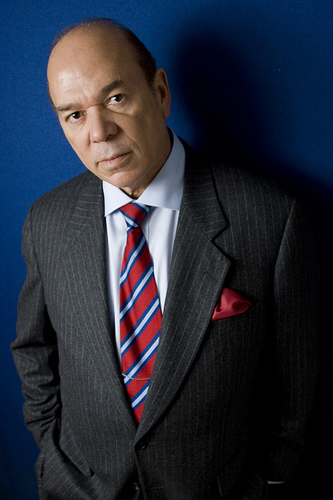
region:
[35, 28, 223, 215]
a man standing inside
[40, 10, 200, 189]
a man with short hair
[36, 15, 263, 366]
a man wearing a shirt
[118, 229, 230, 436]
white blue red tie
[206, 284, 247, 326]
handkerchief in man suit jacket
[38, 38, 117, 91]
man with a bald head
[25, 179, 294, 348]
man wearing a pinstrip jacket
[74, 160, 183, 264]
man wearing a white shirt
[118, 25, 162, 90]
man with black hair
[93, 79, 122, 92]
man with bushy eyebrow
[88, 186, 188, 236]
man wearing a white shirt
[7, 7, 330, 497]
a man looking at the camera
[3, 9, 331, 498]
a person posing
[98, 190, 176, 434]
a red, white, and blue tie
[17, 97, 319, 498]
a black suit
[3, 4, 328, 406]
a blue background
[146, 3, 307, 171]
a shadow in the background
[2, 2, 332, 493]
a single person in image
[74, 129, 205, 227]
a white collar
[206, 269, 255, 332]
a red object in the pocket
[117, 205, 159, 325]
this is a tie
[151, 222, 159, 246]
this is a white shirt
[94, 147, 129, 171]
the mouth if a man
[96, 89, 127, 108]
the eye of the man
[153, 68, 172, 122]
the ear of the man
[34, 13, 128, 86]
man has bald head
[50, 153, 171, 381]
man has white shirt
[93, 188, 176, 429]
red white and blue tie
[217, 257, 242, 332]
man has red kerchief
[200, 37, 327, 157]
shadow on wall behind man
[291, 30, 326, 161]
blue wall behind man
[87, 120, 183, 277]
light blue collared shirt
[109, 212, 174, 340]
white stripe on tie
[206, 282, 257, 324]
red handkerchief in the pocket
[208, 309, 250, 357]
pocket on a jacket's breast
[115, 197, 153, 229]
knot on a tie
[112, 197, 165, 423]
red white and blue tie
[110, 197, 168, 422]
the tie is red and blue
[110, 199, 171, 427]
the tie has stripes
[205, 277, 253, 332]
handkerchief is in a pocket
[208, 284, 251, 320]
handkerchief is color red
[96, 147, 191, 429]
the shirt is color blue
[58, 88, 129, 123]
the eyes are black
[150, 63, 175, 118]
left ear of a man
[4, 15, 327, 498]
man wears a black jacket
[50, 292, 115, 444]
jacket has lines